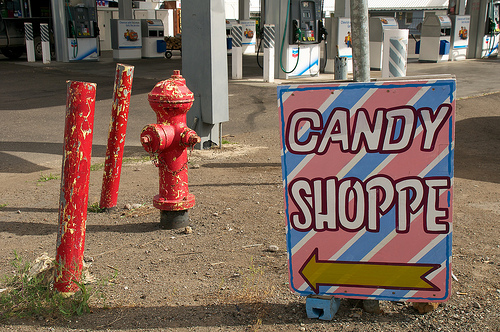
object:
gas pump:
[258, 0, 319, 80]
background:
[0, 0, 500, 150]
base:
[160, 209, 189, 230]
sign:
[277, 75, 459, 303]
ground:
[0, 61, 500, 332]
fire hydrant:
[140, 70, 201, 230]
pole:
[232, 24, 243, 79]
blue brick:
[306, 297, 341, 321]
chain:
[150, 148, 192, 175]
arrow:
[298, 247, 441, 295]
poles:
[23, 23, 51, 64]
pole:
[99, 64, 134, 212]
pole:
[54, 80, 96, 299]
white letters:
[289, 106, 448, 153]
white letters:
[291, 177, 446, 231]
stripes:
[357, 177, 455, 262]